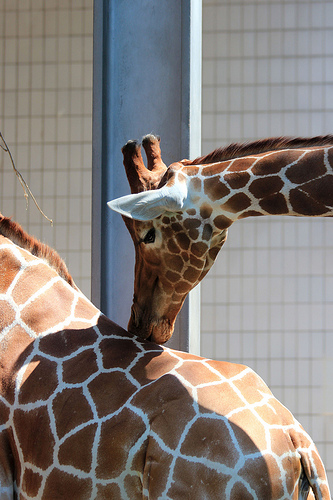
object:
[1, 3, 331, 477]
wall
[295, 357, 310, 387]
tile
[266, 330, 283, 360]
tile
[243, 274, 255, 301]
tile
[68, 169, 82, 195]
tile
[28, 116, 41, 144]
tile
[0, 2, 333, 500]
zoo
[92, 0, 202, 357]
beam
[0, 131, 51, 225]
tree branch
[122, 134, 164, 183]
horns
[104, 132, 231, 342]
head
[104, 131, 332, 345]
brown giraffe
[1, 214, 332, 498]
brown giraffe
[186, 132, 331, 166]
hair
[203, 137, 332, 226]
neck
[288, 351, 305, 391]
tile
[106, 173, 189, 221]
ear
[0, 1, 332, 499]
building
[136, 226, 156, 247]
eye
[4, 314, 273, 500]
shade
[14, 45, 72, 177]
back wall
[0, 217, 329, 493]
giraffe coats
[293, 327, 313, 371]
tile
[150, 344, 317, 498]
rear